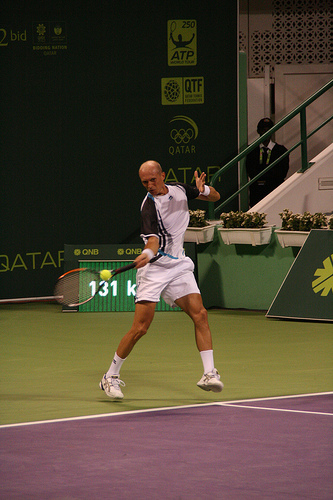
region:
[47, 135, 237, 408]
a man playing tennis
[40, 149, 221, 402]
a man hitting a tennis ball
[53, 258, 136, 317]
a tennis ball and racquet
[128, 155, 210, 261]
a man wearing a black and white shirt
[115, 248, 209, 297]
a man wearing white shorts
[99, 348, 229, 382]
a man wearing white socks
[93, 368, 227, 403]
a man wearing tennis soes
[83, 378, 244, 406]
a man is off the ground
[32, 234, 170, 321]
a man swinging a tennis racquet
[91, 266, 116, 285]
a tennis ball in the air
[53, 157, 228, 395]
the man is playing tennis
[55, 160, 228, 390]
the man hit the ball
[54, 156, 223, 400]
the man has a tennis racket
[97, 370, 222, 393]
the shoes are white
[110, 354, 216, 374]
the socks are white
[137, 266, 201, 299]
the shorts are white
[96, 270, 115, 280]
the ball is yellow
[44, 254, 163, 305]
the racket is red and black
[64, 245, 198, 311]
the sign is black green and white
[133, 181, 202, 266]
the shirt is white blue and black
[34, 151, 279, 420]
a man swinging a tennis racket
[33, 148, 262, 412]
a tennis player hitting a ball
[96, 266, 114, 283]
a yellow tennis ball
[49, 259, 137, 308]
a tennis racket hitting a ball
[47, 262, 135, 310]
an orange and black tennis racket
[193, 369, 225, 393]
a white tennis shoe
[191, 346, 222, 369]
a white tennis sock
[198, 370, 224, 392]
the foot of a tennis player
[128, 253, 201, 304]
a pair of white tennis shorts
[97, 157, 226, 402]
Man in white playing tennis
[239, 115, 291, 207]
Man in a black suit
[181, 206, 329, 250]
Three white planters with flowers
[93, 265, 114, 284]
Green tennis ball in play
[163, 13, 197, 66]
Top green sign with black letters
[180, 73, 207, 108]
Green sign with black letters QTF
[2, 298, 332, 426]
Green section of the tennis courts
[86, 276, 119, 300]
White numbers 131 behind man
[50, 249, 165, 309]
Tennis racket the man is holding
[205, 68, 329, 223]
Green metal railing behind the man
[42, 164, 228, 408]
A man is playing tennis.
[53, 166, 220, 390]
A man is hitting a tennis ball.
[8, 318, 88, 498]
A tennis court has green white and purple floors.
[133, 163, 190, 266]
A man wearing a multi colored shirt.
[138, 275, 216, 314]
A man is wearing white shorts.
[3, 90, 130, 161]
There is a dark green wall behind the man.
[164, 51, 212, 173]
There is gold logos on a wall.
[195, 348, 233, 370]
A man is wearing white tubed socks.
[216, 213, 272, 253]
There are flowers on a green wall.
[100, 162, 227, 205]
A man is wearing a white wrist band.